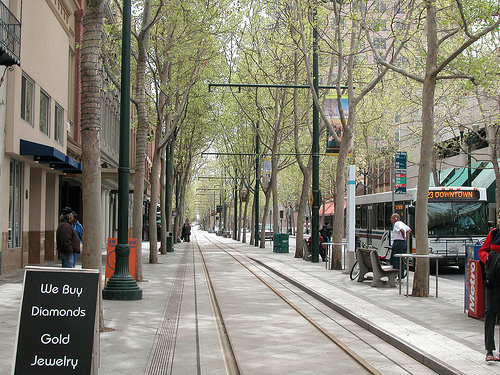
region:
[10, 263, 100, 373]
A black sign with white text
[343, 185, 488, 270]
A white bus stopped at the side of the road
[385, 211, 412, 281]
A black man in a white shirt beside a bench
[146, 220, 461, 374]
Train or rail car tracks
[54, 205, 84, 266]
A man in a hat and brown jacket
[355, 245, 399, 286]
A bench with a bike against it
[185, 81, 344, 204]
Rail car cables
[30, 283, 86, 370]
Text saying "We Buy Diamonds" and "Gold Jewelry"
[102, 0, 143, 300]
A green, old fashioned light pole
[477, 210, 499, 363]
A skinny person in a red and black jacket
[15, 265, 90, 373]
we buy diamonds gold jewelry sign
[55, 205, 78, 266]
man with brown jacket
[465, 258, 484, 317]
red metro box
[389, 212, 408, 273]
man in white shirt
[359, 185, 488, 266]
white downtown bus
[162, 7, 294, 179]
trees over the road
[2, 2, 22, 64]
black balcony on building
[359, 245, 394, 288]
gray bench by the man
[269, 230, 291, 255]
green garbage can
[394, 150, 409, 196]
signs with words on them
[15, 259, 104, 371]
White writing on a black sign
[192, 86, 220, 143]
Green leaves on a tree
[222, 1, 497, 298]
Row of tall trees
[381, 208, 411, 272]
Man wearing a white shirt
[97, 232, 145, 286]
Orange trash bin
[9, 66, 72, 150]
Windows on a building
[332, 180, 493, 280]
A city bus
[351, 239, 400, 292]
Empty bench on the sidewalk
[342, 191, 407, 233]
Windows on the bus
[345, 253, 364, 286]
A round bicycle wheel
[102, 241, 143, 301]
metal round light pole base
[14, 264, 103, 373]
black store advertising sign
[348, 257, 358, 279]
round bicycle tire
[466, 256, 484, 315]
short red newspaper dispenser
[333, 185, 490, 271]
passenger bus on road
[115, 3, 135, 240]
tall metal light pole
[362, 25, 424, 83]
bent tree branch without leaves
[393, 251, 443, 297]
metal protective tree rail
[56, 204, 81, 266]
male in brown coat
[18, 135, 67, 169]
blue awning over doorway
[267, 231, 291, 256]
A green trashcan.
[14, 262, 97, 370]
A black sign with white wording.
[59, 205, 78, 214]
A dark colored hat.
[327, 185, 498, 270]
A city bus.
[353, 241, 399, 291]
A bench.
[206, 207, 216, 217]
A street light on red.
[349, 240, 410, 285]
A bicycle leaned against a bench.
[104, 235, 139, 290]
An orange and blue sign infront of a building.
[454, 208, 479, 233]
A bus driver.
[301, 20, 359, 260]
A sign hanging up on a green pole.